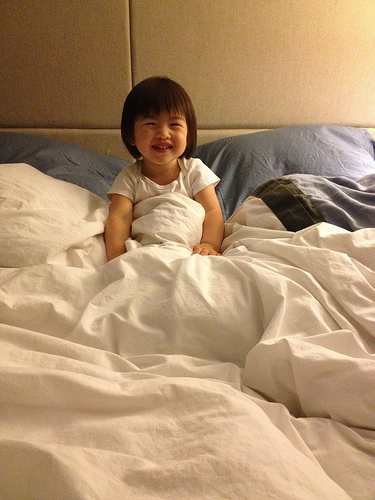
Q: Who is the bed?
A: Little girl.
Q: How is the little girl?
A: Happy.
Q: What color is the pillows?
A: Blue.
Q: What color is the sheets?
A: White.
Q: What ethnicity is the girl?
A: Asian.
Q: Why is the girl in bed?
A: Sleep Time.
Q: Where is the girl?
A: Bed.